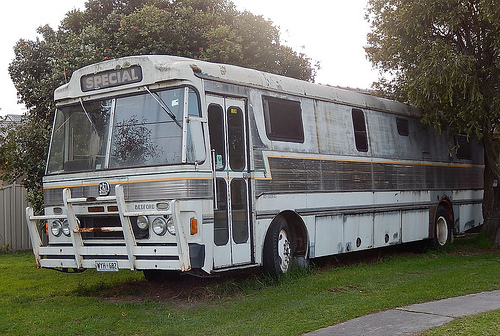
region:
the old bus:
[25, 55, 487, 275]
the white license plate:
[93, 258, 119, 270]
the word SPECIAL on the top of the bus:
[75, 67, 148, 90]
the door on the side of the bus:
[197, 80, 252, 263]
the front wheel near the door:
[265, 214, 298, 283]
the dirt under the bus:
[108, 277, 201, 307]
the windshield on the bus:
[47, 102, 198, 171]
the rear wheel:
[432, 207, 450, 248]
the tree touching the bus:
[361, 2, 497, 139]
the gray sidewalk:
[366, 298, 475, 331]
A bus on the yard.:
[18, 53, 489, 299]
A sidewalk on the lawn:
[317, 286, 499, 333]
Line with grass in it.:
[390, 303, 465, 334]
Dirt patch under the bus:
[77, 264, 241, 311]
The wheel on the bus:
[265, 219, 300, 283]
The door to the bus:
[197, 91, 259, 271]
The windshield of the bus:
[54, 83, 186, 176]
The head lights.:
[37, 199, 187, 249]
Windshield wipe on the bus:
[145, 87, 185, 130]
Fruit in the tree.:
[60, 11, 252, 61]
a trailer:
[154, 35, 371, 295]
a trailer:
[111, 90, 322, 325]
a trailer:
[77, 7, 264, 322]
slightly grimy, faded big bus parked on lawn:
[15, 42, 492, 295]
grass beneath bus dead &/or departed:
[57, 221, 498, 310]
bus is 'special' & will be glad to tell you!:
[75, 61, 145, 93]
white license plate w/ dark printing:
[87, 255, 119, 275]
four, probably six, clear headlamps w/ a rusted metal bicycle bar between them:
[43, 214, 177, 240]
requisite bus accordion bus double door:
[200, 86, 255, 276]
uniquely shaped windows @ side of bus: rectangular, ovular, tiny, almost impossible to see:
[255, 91, 476, 168]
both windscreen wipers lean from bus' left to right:
[65, 80, 186, 147]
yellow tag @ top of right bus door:
[227, 103, 239, 114]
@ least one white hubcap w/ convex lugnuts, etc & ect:
[265, 221, 309, 271]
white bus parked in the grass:
[23, 37, 485, 294]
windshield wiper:
[141, 81, 188, 127]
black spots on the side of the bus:
[324, 211, 366, 223]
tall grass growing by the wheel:
[253, 260, 319, 287]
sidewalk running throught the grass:
[306, 281, 498, 335]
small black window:
[351, 107, 374, 152]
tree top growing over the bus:
[363, 1, 493, 148]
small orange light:
[188, 216, 198, 235]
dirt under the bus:
[82, 276, 234, 313]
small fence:
[3, 178, 48, 255]